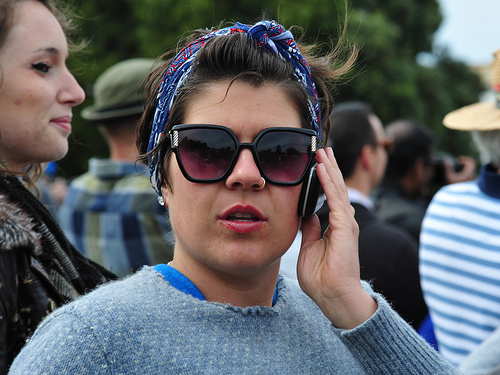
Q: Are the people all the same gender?
A: No, they are both male and female.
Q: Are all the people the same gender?
A: No, they are both male and female.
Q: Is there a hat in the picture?
A: Yes, there is a hat.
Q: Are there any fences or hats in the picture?
A: Yes, there is a hat.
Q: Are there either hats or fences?
A: Yes, there is a hat.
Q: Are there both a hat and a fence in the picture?
A: No, there is a hat but no fences.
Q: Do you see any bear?
A: No, there are no bears.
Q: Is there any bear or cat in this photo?
A: No, there are no bears or cats.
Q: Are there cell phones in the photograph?
A: Yes, there is a cell phone.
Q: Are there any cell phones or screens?
A: Yes, there is a cell phone.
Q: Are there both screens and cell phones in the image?
A: No, there is a cell phone but no screens.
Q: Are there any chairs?
A: No, there are no chairs.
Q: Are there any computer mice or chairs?
A: No, there are no chairs or computer mice.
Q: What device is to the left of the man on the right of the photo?
A: The device is a cell phone.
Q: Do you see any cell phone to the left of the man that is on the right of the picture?
A: Yes, there is a cell phone to the left of the man.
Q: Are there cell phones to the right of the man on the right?
A: No, the cell phone is to the left of the man.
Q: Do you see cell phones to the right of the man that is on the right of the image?
A: No, the cell phone is to the left of the man.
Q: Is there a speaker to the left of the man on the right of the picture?
A: No, there is a cell phone to the left of the man.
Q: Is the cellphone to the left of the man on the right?
A: Yes, the cellphone is to the left of the man.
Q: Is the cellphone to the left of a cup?
A: No, the cellphone is to the left of the man.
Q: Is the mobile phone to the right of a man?
A: No, the mobile phone is to the left of a man.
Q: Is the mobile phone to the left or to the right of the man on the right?
A: The mobile phone is to the left of the man.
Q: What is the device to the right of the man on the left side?
A: The device is a cell phone.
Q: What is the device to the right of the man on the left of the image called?
A: The device is a cell phone.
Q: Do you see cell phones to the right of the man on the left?
A: Yes, there is a cell phone to the right of the man.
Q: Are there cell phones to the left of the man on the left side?
A: No, the cell phone is to the right of the man.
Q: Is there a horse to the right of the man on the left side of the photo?
A: No, there is a cell phone to the right of the man.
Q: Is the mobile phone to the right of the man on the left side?
A: Yes, the mobile phone is to the right of the man.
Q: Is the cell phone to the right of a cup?
A: No, the cell phone is to the right of the man.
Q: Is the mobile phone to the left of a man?
A: No, the mobile phone is to the right of a man.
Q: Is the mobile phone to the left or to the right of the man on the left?
A: The mobile phone is to the right of the man.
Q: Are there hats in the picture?
A: Yes, there is a hat.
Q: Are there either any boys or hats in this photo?
A: Yes, there is a hat.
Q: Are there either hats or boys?
A: Yes, there is a hat.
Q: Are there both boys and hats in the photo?
A: No, there is a hat but no boys.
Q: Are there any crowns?
A: No, there are no crowns.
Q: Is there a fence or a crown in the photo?
A: No, there are no crowns or fences.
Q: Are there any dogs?
A: No, there are no dogs.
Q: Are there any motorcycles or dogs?
A: No, there are no dogs or motorcycles.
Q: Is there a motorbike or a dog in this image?
A: No, there are no dogs or motorcycles.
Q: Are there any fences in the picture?
A: No, there are no fences.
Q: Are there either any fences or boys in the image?
A: No, there are no fences or boys.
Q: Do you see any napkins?
A: No, there are no napkins.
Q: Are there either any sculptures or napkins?
A: No, there are no napkins or sculptures.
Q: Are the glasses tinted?
A: Yes, the glasses are tinted.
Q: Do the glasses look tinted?
A: Yes, the glasses are tinted.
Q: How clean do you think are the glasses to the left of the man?
A: The glasses are tinted.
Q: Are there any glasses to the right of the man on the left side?
A: Yes, there are glasses to the right of the man.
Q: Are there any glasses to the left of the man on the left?
A: No, the glasses are to the right of the man.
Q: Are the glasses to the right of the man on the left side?
A: Yes, the glasses are to the right of the man.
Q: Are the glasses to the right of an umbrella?
A: No, the glasses are to the right of the man.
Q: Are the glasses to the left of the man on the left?
A: No, the glasses are to the right of the man.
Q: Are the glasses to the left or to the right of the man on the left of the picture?
A: The glasses are to the right of the man.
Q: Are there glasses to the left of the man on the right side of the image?
A: Yes, there are glasses to the left of the man.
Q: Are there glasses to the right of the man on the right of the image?
A: No, the glasses are to the left of the man.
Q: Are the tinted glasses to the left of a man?
A: Yes, the glasses are to the left of a man.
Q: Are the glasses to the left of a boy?
A: No, the glasses are to the left of a man.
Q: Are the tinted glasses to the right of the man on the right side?
A: No, the glasses are to the left of the man.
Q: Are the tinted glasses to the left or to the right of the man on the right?
A: The glasses are to the left of the man.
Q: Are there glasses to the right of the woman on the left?
A: Yes, there are glasses to the right of the woman.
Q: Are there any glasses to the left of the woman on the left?
A: No, the glasses are to the right of the woman.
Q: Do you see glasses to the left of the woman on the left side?
A: No, the glasses are to the right of the woman.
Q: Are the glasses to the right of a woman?
A: Yes, the glasses are to the right of a woman.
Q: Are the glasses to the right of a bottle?
A: No, the glasses are to the right of a woman.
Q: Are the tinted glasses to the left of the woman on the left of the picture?
A: No, the glasses are to the right of the woman.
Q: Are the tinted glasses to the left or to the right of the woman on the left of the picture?
A: The glasses are to the right of the woman.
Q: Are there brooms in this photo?
A: No, there are no brooms.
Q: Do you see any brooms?
A: No, there are no brooms.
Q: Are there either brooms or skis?
A: No, there are no brooms or skis.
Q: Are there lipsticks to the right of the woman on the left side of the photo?
A: Yes, there is a lipstick to the right of the woman.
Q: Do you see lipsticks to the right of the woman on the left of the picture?
A: Yes, there is a lipstick to the right of the woman.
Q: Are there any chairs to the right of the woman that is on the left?
A: No, there is a lipstick to the right of the woman.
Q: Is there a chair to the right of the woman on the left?
A: No, there is a lipstick to the right of the woman.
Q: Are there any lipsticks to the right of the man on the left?
A: Yes, there is a lipstick to the right of the man.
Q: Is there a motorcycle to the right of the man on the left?
A: No, there is a lipstick to the right of the man.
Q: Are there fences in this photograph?
A: No, there are no fences.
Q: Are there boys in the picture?
A: No, there are no boys.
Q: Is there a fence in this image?
A: No, there are no fences.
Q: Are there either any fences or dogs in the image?
A: No, there are no fences or dogs.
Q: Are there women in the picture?
A: Yes, there is a woman.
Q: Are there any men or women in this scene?
A: Yes, there is a woman.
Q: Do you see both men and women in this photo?
A: Yes, there are both a woman and a man.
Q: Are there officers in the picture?
A: No, there are no officers.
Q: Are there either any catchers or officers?
A: No, there are no officers or catchers.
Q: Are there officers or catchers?
A: No, there are no officers or catchers.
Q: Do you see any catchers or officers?
A: No, there are no officers or catchers.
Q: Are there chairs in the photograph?
A: No, there are no chairs.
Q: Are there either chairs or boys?
A: No, there are no chairs or boys.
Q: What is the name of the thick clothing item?
A: The clothing item is a sweater.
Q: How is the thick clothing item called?
A: The clothing item is a sweater.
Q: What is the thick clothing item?
A: The clothing item is a sweater.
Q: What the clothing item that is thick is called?
A: The clothing item is a sweater.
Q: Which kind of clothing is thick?
A: The clothing is a sweater.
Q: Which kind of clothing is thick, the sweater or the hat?
A: The sweater is thick.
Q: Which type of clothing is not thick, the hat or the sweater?
A: The hat is not thick.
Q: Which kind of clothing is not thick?
A: The clothing is a hat.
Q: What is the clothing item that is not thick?
A: The clothing item is a hat.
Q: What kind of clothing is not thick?
A: The clothing is a hat.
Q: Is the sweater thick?
A: Yes, the sweater is thick.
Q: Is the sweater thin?
A: No, the sweater is thick.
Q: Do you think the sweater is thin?
A: No, the sweater is thick.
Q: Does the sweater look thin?
A: No, the sweater is thick.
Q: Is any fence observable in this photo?
A: No, there are no fences.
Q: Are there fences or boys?
A: No, there are no fences or boys.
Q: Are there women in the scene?
A: Yes, there is a woman.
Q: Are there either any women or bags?
A: Yes, there is a woman.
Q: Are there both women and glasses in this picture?
A: Yes, there are both a woman and glasses.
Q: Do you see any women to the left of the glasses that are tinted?
A: Yes, there is a woman to the left of the glasses.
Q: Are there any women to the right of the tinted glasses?
A: No, the woman is to the left of the glasses.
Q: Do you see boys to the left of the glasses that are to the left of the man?
A: No, there is a woman to the left of the glasses.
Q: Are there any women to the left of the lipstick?
A: Yes, there is a woman to the left of the lipstick.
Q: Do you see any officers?
A: No, there are no officers.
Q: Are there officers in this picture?
A: No, there are no officers.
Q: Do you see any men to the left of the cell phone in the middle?
A: Yes, there is a man to the left of the mobile phone.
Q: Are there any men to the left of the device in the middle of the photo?
A: Yes, there is a man to the left of the mobile phone.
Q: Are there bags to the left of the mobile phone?
A: No, there is a man to the left of the mobile phone.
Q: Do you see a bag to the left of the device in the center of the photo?
A: No, there is a man to the left of the mobile phone.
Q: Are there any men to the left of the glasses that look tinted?
A: Yes, there is a man to the left of the glasses.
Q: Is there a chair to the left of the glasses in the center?
A: No, there is a man to the left of the glasses.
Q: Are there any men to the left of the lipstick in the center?
A: Yes, there is a man to the left of the lipstick.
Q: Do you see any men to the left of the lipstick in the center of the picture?
A: Yes, there is a man to the left of the lipstick.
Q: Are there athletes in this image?
A: No, there are no athletes.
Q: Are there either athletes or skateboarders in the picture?
A: No, there are no athletes or skateboarders.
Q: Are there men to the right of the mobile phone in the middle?
A: Yes, there is a man to the right of the cell phone.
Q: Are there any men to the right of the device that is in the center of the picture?
A: Yes, there is a man to the right of the cell phone.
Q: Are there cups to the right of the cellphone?
A: No, there is a man to the right of the cellphone.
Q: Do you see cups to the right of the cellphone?
A: No, there is a man to the right of the cellphone.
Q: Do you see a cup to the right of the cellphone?
A: No, there is a man to the right of the cellphone.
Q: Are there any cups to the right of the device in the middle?
A: No, there is a man to the right of the cellphone.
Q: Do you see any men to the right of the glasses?
A: Yes, there is a man to the right of the glasses.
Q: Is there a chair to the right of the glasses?
A: No, there is a man to the right of the glasses.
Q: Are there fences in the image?
A: No, there are no fences.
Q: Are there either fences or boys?
A: No, there are no fences or boys.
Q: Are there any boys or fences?
A: No, there are no fences or boys.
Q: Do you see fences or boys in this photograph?
A: No, there are no fences or boys.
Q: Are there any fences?
A: No, there are no fences.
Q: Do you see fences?
A: No, there are no fences.